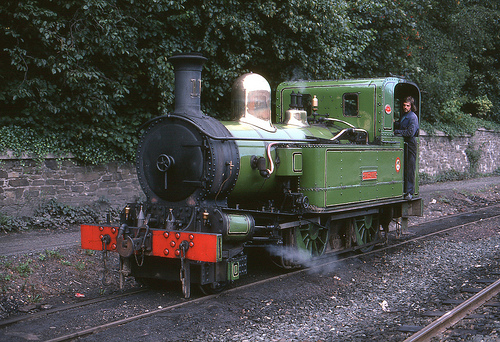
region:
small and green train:
[150, 49, 453, 290]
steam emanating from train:
[226, 215, 397, 305]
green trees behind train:
[8, 14, 188, 117]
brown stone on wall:
[4, 130, 158, 227]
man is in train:
[369, 68, 419, 203]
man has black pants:
[405, 144, 425, 199]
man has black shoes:
[381, 189, 421, 221]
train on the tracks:
[81, 38, 468, 298]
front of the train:
[103, 88, 252, 275]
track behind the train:
[430, 183, 487, 257]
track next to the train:
[405, 269, 491, 339]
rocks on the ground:
[335, 255, 434, 325]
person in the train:
[376, 83, 436, 173]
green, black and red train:
[109, 64, 424, 274]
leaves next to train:
[43, 11, 167, 93]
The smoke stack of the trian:
[163, 38, 208, 116]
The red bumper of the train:
[86, 218, 226, 259]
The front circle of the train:
[139, 112, 223, 200]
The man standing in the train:
[390, 95, 421, 219]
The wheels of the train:
[285, 216, 420, 256]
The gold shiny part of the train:
[240, 61, 272, 131]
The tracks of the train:
[389, 248, 496, 339]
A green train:
[103, 75, 424, 279]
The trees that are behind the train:
[13, 15, 498, 177]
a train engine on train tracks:
[74, 45, 436, 303]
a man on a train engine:
[386, 78, 424, 208]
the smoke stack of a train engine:
[160, 40, 212, 120]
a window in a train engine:
[339, 88, 360, 123]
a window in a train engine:
[285, 88, 320, 111]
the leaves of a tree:
[50, 47, 100, 92]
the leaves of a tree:
[390, 30, 445, 70]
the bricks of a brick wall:
[16, 166, 77, 206]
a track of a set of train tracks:
[415, 282, 485, 337]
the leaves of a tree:
[306, 33, 346, 65]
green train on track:
[138, 45, 453, 272]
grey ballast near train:
[233, 255, 355, 339]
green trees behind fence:
[22, 25, 145, 92]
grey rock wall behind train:
[4, 128, 179, 274]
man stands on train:
[397, 85, 450, 217]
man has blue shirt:
[401, 85, 427, 155]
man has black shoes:
[388, 160, 423, 203]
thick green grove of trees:
[19, 17, 452, 92]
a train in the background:
[87, 40, 496, 310]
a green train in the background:
[89, 28, 469, 327]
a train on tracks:
[62, 44, 496, 296]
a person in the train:
[376, 76, 450, 233]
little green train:
[87, 63, 425, 293]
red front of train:
[79, 219, 222, 264]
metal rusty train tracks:
[11, 203, 498, 340]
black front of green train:
[134, 54, 236, 207]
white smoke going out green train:
[254, 243, 338, 278]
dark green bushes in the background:
[2, 2, 495, 171]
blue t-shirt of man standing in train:
[396, 108, 416, 138]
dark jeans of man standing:
[401, 135, 416, 192]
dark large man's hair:
[401, 97, 417, 114]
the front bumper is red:
[73, 220, 227, 266]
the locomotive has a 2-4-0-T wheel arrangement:
[75, 62, 427, 294]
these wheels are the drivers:
[287, 201, 377, 261]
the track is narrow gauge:
[1, 200, 493, 340]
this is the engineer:
[391, 90, 423, 197]